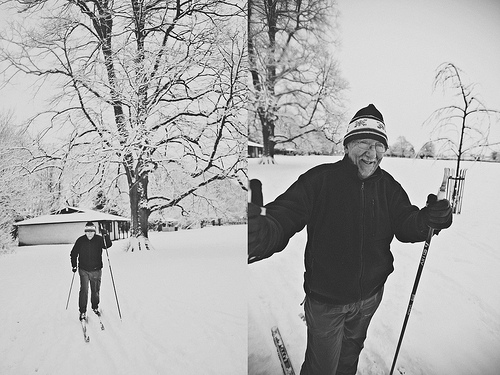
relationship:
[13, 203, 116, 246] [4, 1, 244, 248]
building by tree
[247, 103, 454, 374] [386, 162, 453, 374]
he has pole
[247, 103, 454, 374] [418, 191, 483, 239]
he has hand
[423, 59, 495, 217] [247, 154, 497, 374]
tree in snow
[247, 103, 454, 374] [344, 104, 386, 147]
he wears cap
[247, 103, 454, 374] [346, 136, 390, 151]
he has eye glasses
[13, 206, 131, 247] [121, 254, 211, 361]
building covered in snow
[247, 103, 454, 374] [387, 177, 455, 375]
he holding pole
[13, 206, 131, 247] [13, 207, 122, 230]
building with roof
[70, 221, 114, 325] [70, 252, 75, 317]
he with skis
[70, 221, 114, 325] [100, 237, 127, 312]
he with skis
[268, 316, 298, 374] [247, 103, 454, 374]
ski of he